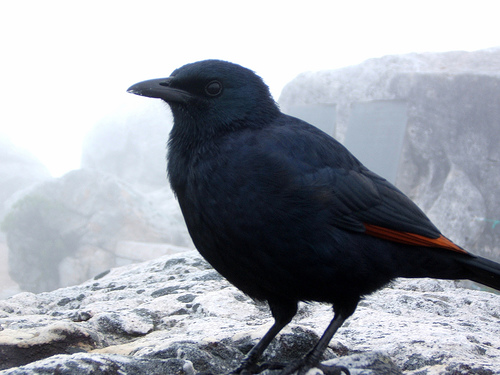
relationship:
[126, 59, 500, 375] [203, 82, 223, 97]
bird has eye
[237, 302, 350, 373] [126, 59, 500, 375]
legs of bird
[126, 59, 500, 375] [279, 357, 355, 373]
bird has foot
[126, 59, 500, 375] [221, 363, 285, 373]
bird has foot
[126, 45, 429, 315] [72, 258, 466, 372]
bird standing on rock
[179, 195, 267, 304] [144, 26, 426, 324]
belly of bird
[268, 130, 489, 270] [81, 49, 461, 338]
feathers of black bird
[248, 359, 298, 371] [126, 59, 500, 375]
claw of bird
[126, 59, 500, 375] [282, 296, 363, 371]
bird with leg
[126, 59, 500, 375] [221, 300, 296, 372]
bird with leg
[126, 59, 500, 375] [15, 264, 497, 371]
bird on rocks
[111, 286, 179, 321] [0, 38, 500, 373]
rocks on mountain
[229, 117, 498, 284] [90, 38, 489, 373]
wing of bird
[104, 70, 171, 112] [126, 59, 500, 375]
beak of bird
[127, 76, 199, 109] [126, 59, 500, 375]
beak of bird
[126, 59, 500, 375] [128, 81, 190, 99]
bird has beak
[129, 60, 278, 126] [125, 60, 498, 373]
head of black bird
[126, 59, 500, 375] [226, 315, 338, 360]
bird on rock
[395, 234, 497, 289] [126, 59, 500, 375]
tail of bird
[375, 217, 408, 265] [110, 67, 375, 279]
red feathers on blackbird